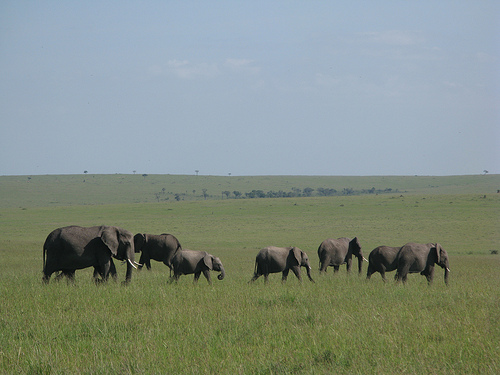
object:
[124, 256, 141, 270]
tusk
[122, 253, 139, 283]
trunks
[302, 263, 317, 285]
trunks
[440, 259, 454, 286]
trunks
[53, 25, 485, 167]
clouds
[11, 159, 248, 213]
hill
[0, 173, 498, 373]
field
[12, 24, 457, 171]
sky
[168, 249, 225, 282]
baby elephant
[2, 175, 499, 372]
grass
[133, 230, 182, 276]
elephant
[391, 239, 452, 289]
baby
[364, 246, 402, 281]
baby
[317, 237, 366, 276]
baby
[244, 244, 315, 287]
baby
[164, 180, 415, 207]
trees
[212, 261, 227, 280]
trunk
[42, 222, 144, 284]
adult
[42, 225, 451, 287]
herd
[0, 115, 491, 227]
background